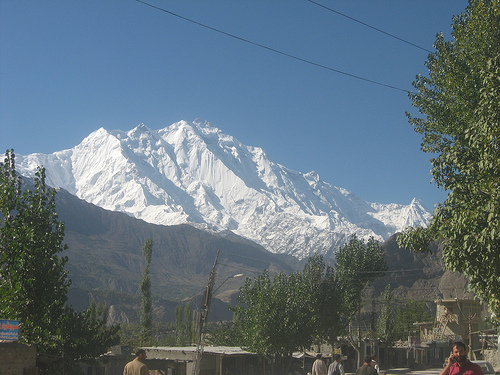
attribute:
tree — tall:
[406, 0, 498, 330]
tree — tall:
[393, 23, 498, 277]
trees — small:
[242, 267, 357, 334]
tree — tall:
[2, 147, 74, 322]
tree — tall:
[21, 298, 123, 370]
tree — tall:
[330, 228, 392, 316]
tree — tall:
[222, 268, 323, 366]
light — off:
[229, 271, 246, 282]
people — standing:
[304, 333, 378, 373]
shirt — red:
[445, 357, 482, 371]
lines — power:
[125, 0, 497, 102]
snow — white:
[173, 134, 276, 202]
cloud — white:
[5, 107, 99, 164]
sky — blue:
[8, 10, 169, 105]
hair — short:
[136, 347, 140, 359]